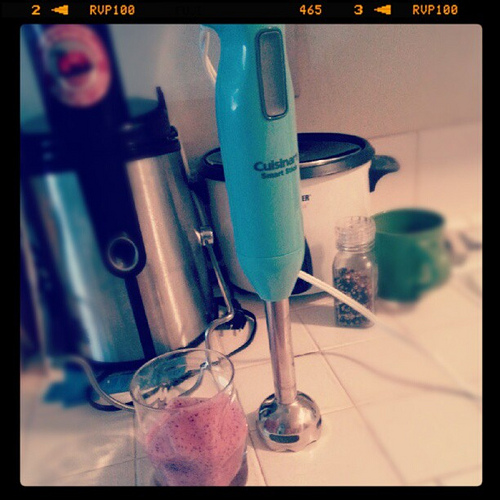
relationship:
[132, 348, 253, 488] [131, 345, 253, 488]
smoothie inside a glass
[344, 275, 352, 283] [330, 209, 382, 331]
peppercorn inside a pepper grinder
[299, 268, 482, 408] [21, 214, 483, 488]
electrical cord on top of kitchen counter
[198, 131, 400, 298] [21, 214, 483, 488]
appliance on top of kitchen counter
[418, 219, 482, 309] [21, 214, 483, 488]
sink meeting kitchen counter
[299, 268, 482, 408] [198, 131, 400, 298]
electrical cord used for appliance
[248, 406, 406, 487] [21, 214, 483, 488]
ceramic tile on top of kitchen counter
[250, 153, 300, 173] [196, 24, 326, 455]
company logo written on immerision blender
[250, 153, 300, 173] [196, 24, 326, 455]
company logo on side of immerision blender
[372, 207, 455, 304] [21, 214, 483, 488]
mug on top of kitchen counter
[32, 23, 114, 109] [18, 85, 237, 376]
design printed on front of appliance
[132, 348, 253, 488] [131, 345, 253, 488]
smoothie poured in a glass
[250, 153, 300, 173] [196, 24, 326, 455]
company logo printed on immerision blender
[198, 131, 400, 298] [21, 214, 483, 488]
appliance on top of a kitchen counter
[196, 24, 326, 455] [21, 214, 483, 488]
immerision blender on top of kitchen counter